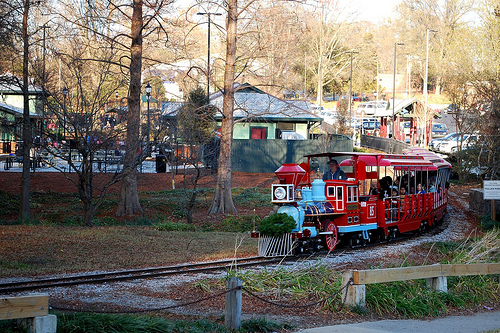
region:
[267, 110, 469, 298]
this is a red train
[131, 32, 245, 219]
these are brown trees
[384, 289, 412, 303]
this is green grass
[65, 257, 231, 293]
these are train tracks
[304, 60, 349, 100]
these are green leaves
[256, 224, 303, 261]
this is a train guard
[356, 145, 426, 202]
this is a train card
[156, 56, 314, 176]
this is a house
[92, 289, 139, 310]
these are gravel rocks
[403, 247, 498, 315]
these are brown weeds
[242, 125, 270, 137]
a window of a building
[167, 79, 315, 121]
a brown roof of a building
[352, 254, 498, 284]
a long wooden post fence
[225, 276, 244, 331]
a wooden short pole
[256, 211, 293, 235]
an evergreen wreath on train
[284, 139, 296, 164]
a smoke stack on a train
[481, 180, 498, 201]
a white sign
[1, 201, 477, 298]
a pair of rusty train tracks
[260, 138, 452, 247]
a long red train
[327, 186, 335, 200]
a small window of a train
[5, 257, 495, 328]
fencing guarding train tracks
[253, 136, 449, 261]
red, white, and light blue childrens train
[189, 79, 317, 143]
light green building with red door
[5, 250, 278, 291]
railroad tracks for childrens train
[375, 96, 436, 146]
tram pavilion for waiting passengers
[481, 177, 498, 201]
black and white informational sign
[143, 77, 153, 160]
black cast iron lamp post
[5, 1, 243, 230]
trees in park area behind train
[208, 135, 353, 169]
dark green fence in front of building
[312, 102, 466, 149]
cars parked in parking lot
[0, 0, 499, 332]
small train at a park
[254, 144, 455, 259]
small train turning a corner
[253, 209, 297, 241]
Christmas wreath on train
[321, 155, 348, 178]
engineer driving the train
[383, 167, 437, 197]
passengers on the train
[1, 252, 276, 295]
track for the train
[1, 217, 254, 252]
grassy area in park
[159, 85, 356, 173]
green building behind fence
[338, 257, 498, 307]
wooden railing on blocks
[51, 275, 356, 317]
chain between the railings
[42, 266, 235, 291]
train track by grass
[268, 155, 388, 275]
red train on tracks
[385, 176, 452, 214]
people riding on red train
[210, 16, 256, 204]
tree with no leaves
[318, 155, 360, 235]
conductor of red train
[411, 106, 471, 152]
cars in parking lot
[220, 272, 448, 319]
chains and boards to make fence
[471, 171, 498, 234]
sign by train track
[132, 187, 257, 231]
grass around trees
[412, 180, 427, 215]
person in blue shirt